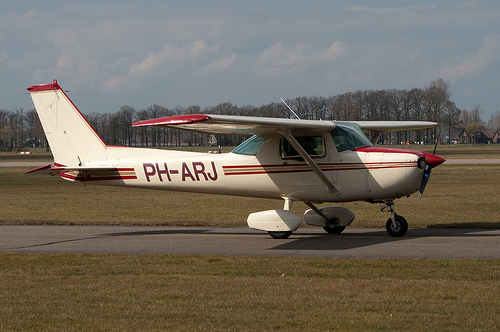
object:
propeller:
[417, 152, 444, 196]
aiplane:
[24, 68, 445, 240]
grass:
[10, 154, 497, 330]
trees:
[425, 78, 450, 146]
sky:
[393, 5, 497, 61]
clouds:
[136, 40, 218, 77]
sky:
[52, 1, 124, 22]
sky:
[169, 1, 346, 33]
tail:
[24, 78, 126, 188]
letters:
[170, 170, 179, 175]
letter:
[143, 163, 157, 183]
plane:
[12, 70, 445, 257]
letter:
[155, 163, 172, 182]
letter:
[182, 162, 196, 181]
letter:
[192, 162, 208, 181]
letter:
[208, 162, 218, 181]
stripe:
[222, 161, 416, 176]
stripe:
[80, 166, 139, 180]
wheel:
[385, 215, 409, 238]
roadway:
[139, 224, 203, 250]